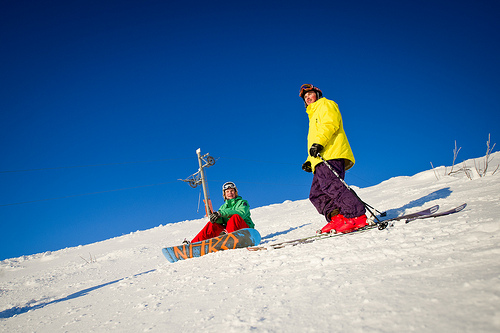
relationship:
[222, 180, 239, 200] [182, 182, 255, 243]
helmet on boy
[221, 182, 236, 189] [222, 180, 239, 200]
googles on helmet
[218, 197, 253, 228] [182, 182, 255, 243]
jacket on boy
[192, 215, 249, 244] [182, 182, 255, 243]
pants on boy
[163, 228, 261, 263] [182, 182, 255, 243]
snowboard on boy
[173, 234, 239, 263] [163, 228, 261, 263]
letters on snowboard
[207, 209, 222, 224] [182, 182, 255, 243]
gloves on boy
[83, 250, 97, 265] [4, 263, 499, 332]
weeds in snow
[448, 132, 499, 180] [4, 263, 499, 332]
branches in snow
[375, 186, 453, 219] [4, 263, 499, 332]
shadow on snow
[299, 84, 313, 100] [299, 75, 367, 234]
googles on man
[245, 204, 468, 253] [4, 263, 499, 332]
skis in snow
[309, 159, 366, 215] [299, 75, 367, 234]
pants on man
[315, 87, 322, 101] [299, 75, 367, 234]
helmet on man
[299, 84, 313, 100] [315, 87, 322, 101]
googles on helmet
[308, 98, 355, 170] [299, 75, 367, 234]
jecket on man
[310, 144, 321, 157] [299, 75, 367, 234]
glove on man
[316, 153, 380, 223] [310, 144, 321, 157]
pole in hand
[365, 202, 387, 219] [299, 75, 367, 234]
pole of man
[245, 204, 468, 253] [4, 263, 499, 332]
skis on snow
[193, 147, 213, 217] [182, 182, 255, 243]
pole behind boy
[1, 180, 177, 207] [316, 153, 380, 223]
wires on pole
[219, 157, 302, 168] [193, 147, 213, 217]
wires on pole